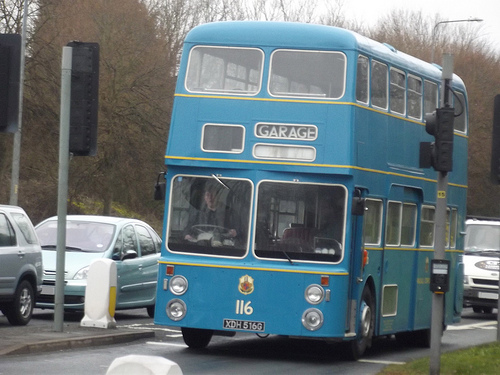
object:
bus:
[149, 19, 472, 364]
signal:
[418, 106, 456, 173]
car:
[32, 214, 164, 319]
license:
[254, 121, 319, 142]